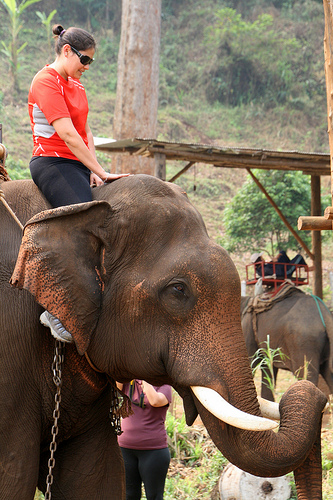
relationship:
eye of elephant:
[156, 271, 199, 305] [5, 159, 320, 494]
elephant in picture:
[5, 159, 320, 494] [1, 5, 325, 499]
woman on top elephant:
[20, 15, 137, 208] [5, 159, 320, 494]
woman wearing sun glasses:
[20, 15, 137, 208] [67, 43, 104, 68]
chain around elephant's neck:
[35, 344, 75, 491] [32, 198, 139, 398]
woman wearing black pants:
[20, 15, 137, 208] [30, 156, 99, 212]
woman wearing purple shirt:
[118, 381, 183, 499] [115, 384, 173, 456]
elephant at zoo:
[5, 159, 320, 494] [1, 5, 325, 499]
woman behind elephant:
[118, 381, 183, 499] [5, 159, 320, 494]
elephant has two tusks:
[5, 159, 320, 494] [185, 369, 325, 445]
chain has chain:
[35, 344, 75, 491] [46, 333, 65, 491]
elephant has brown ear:
[5, 159, 320, 494] [2, 195, 126, 366]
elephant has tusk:
[5, 159, 320, 494] [185, 378, 281, 442]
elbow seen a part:
[144, 385, 169, 413] [145, 395, 167, 410]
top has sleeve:
[23, 68, 96, 164] [32, 74, 76, 130]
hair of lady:
[37, 17, 106, 87] [20, 15, 137, 208]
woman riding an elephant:
[20, 15, 137, 208] [5, 159, 320, 494]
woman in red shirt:
[20, 15, 137, 208] [23, 68, 96, 164]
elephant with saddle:
[239, 240, 331, 403] [236, 246, 317, 304]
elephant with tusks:
[5, 159, 320, 494] [185, 369, 325, 445]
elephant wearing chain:
[5, 159, 320, 494] [35, 344, 75, 491]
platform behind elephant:
[96, 133, 332, 180] [5, 159, 320, 494]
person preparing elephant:
[20, 15, 137, 208] [5, 159, 320, 494]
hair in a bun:
[37, 17, 106, 87] [46, 19, 78, 44]